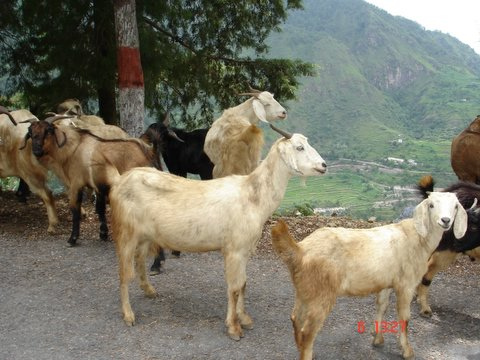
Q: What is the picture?
A: Goats.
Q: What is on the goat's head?
A: Horns.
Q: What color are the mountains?
A: Green.